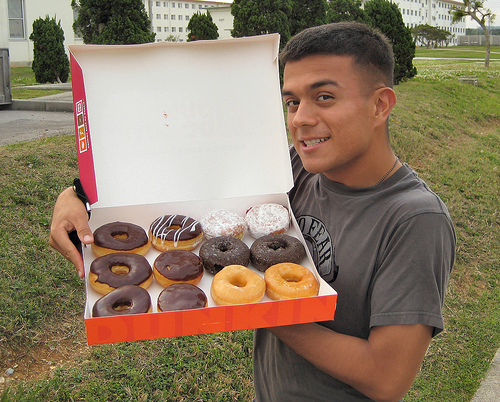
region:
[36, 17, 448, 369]
the boy is holding donuts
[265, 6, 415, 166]
the boy is smiling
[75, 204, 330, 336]
there are 12 donuts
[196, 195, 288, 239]
these donuts are white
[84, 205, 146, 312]
the donuts have chocolate frosting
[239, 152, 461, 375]
the boys shirt is grey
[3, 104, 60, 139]
the ground is grey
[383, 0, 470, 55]
a building in the background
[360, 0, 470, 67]
the building is white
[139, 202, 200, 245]
the donut has white lines on it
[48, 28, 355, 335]
a box of assorted donuts.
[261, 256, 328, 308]
a glazed donut.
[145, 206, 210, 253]
a chocolate and white frosting donut.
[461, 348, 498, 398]
a paved sidewalk.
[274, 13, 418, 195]
a man with a short haircut.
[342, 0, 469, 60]
a white multi story building.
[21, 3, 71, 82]
a short green plant.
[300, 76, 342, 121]
the left eye of a man.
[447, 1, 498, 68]
A tall leafy tree.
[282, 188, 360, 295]
a logo on a shirt.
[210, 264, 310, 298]
two glazed donuts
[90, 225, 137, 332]
three chocolate donuts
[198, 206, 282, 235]
two jelly filled donuts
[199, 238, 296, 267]
two chocolate cake donuts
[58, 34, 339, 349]
a box of donuts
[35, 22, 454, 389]
He is holding a box of donuts.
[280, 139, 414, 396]
He is wearing a grey shirt.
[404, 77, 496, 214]
The grass is dying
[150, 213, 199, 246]
a chocolate and vanilla glazed donut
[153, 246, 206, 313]
two cream filled donuts.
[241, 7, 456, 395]
A man in a gray shirt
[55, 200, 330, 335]
A box of donuts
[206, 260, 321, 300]
Two glazed donuts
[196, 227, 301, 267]
Two chocolate cake donuts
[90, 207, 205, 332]
Six chocolate frosted donuts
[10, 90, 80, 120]
A concrete curb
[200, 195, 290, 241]
Two filled donuts with powder sugar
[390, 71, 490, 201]
A grass covered small hill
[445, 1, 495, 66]
A bowed tree with little leaves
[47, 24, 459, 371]
A man with a dozen donuts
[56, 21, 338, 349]
open box of donuts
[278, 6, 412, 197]
dark haired man smiling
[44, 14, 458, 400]
man holding box of donuts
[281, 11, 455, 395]
man wearing gray t shirt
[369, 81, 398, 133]
left ear of male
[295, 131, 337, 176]
man's mouth and chin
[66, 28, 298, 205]
white inner lid of donut box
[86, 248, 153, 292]
chocolate glazed donut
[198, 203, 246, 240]
powdered filled donut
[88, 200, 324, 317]
twelve donuts in a box